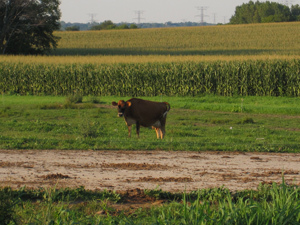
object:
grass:
[26, 95, 93, 142]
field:
[104, 29, 213, 77]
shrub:
[65, 89, 84, 103]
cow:
[111, 98, 171, 140]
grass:
[185, 98, 297, 141]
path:
[1, 149, 299, 191]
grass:
[1, 191, 300, 225]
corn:
[0, 22, 299, 95]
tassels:
[78, 32, 299, 65]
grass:
[0, 94, 299, 151]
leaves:
[0, 0, 61, 54]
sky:
[59, 0, 226, 23]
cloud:
[61, 1, 149, 19]